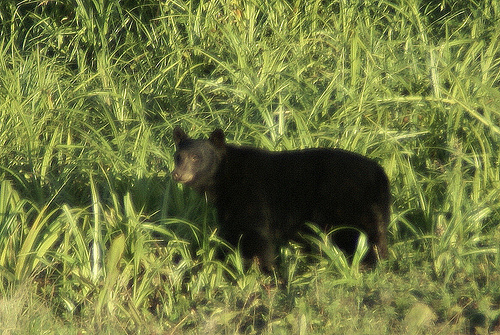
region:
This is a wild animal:
[155, 108, 435, 306]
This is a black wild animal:
[142, 84, 445, 324]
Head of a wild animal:
[161, 116, 230, 194]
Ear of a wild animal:
[206, 118, 228, 154]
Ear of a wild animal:
[166, 118, 194, 148]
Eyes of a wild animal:
[166, 148, 211, 165]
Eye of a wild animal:
[189, 148, 199, 164]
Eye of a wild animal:
[170, 150, 181, 160]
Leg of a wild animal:
[245, 204, 285, 288]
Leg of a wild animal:
[361, 203, 413, 275]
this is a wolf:
[156, 126, 406, 262]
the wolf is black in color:
[246, 155, 301, 192]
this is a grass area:
[22, 52, 168, 257]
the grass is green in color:
[45, 227, 127, 278]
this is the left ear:
[208, 125, 221, 144]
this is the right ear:
[166, 122, 190, 141]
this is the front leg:
[248, 238, 289, 273]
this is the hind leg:
[360, 227, 415, 269]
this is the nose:
[163, 164, 185, 178]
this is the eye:
[188, 150, 198, 160]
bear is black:
[158, 134, 380, 264]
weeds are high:
[0, 111, 120, 291]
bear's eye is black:
[190, 150, 206, 167]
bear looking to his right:
[156, 122, 381, 258]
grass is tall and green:
[5, 11, 431, 101]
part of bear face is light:
[171, 158, 191, 189]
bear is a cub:
[173, 133, 383, 263]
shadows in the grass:
[17, 166, 187, 244]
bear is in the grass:
[170, 132, 406, 277]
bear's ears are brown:
[157, 120, 227, 144]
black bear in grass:
[151, 124, 396, 278]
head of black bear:
[167, 125, 247, 195]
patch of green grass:
[152, 239, 209, 296]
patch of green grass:
[122, 244, 155, 304]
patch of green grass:
[98, 233, 146, 306]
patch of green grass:
[426, 228, 473, 320]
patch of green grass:
[441, 202, 478, 270]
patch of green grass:
[438, 130, 471, 190]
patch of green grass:
[45, 86, 102, 138]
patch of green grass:
[88, 175, 135, 233]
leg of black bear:
[251, 238, 281, 290]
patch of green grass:
[414, 287, 461, 334]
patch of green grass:
[420, 161, 479, 230]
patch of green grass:
[6, 195, 73, 278]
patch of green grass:
[43, 99, 107, 166]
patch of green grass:
[70, 27, 145, 98]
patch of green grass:
[281, 25, 331, 78]